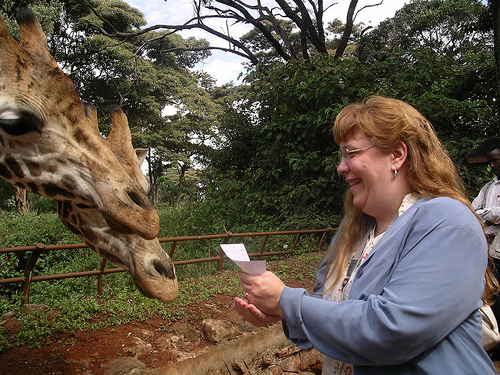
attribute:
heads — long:
[3, 8, 172, 248]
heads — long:
[42, 90, 182, 316]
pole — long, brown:
[0, 223, 340, 256]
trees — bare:
[1, 0, 498, 225]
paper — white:
[210, 219, 286, 281]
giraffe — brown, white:
[0, 1, 183, 306]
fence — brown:
[6, 221, 350, 302]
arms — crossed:
[462, 197, 498, 229]